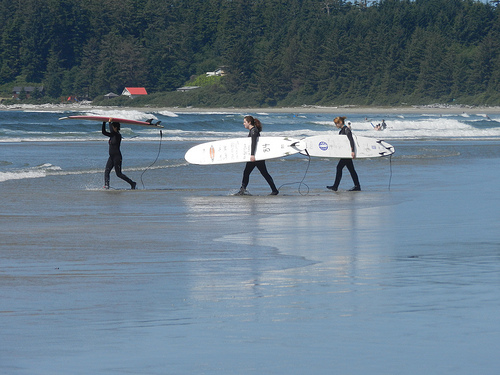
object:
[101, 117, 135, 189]
surfer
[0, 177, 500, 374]
beach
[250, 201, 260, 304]
reflection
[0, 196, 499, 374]
sand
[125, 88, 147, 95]
roof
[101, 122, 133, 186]
black wetsuits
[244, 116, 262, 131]
pony tail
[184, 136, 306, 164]
surfboards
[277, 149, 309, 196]
tether leash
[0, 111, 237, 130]
blue waters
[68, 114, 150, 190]
surfing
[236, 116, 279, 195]
surfer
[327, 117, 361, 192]
surfer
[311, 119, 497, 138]
waves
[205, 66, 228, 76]
building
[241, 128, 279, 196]
wetsuit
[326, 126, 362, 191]
wetsuit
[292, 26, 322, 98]
trees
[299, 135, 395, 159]
surfboard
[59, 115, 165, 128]
surfboard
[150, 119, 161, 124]
fin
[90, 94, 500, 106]
grass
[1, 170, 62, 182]
ripples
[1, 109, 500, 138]
an ocean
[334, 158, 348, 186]
womans leg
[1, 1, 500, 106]
forest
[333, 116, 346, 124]
her hair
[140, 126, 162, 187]
tether line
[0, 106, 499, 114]
shoreline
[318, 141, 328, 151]
logo brand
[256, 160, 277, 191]
legs